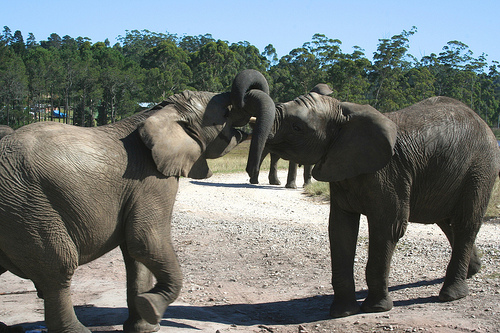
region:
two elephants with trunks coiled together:
[1, 60, 491, 329]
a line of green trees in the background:
[0, 25, 499, 110]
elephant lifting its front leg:
[1, 85, 249, 331]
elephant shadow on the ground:
[210, 260, 490, 331]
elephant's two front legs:
[317, 184, 421, 321]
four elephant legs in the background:
[250, 141, 315, 194]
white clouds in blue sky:
[22, 7, 43, 22]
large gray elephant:
[12, 70, 253, 325]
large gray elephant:
[288, 78, 494, 283]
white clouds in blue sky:
[450, 24, 478, 49]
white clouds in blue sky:
[346, 14, 368, 37]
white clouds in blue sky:
[264, 5, 304, 44]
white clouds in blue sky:
[184, 10, 236, 37]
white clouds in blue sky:
[136, 9, 161, 24]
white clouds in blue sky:
[75, 6, 116, 35]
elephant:
[270, 63, 488, 281]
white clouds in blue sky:
[17, 3, 55, 27]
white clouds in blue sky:
[112, 11, 170, 39]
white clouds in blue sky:
[65, 9, 107, 29]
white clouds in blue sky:
[256, 8, 291, 50]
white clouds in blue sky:
[270, 11, 335, 35]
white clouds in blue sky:
[322, 5, 382, 49]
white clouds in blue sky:
[4, 0, 16, 20]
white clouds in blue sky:
[38, 6, 71, 23]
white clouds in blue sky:
[153, 8, 179, 24]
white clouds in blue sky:
[210, 12, 240, 36]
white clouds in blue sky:
[253, 0, 275, 20]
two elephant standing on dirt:
[0, 62, 499, 331]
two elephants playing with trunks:
[2, 60, 499, 332]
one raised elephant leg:
[123, 233, 195, 328]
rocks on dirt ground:
[221, 219, 303, 294]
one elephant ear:
[302, 99, 411, 189]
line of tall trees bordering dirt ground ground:
[3, 15, 498, 165]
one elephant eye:
[289, 118, 310, 136]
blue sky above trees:
[1, 1, 497, 85]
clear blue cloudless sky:
[0, 0, 496, 22]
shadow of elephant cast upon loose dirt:
[185, 297, 354, 324]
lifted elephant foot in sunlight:
[135, 291, 166, 324]